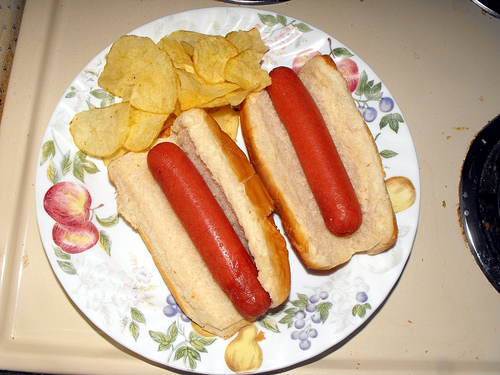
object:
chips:
[69, 101, 134, 160]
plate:
[33, 5, 423, 375]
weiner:
[143, 138, 271, 322]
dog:
[265, 62, 364, 237]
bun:
[239, 53, 401, 273]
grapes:
[294, 319, 305, 329]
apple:
[43, 181, 106, 226]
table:
[0, 0, 498, 370]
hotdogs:
[105, 107, 293, 341]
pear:
[221, 323, 268, 373]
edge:
[457, 161, 480, 237]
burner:
[456, 111, 500, 297]